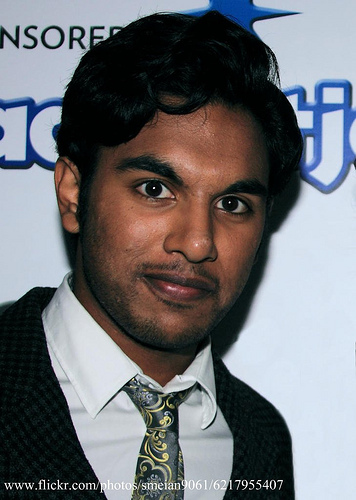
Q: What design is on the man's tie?
A: Paisley.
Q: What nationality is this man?
A: Indian.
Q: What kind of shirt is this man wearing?
A: Dress.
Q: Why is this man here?
A: Famous.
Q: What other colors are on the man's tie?
A: Gold, grey, black.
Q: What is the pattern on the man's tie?
A: Paisley.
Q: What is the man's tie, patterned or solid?
A: Patterned.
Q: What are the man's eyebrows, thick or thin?
A: Thick.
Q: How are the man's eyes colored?
A: Brown.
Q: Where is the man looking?
A: Ahead.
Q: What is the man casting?
A: Shadow.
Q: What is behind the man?
A: Writing.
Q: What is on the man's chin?
A: Hair.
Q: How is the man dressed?
A: Formal.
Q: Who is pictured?
A: A man.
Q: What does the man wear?
A: A tie.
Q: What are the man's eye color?
A: Brown.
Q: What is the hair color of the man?
A: Black.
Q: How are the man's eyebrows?
A: Bushy.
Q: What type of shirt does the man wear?
A: Collared.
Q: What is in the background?
A: White sign.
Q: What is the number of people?
A: One.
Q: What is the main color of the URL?
A: White.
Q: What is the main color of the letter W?
A: White.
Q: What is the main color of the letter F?
A: White.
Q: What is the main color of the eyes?
A: Brown.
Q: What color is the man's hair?
A: Black.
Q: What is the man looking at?
A: The camera.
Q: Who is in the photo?
A: A man.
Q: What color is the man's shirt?
A: White.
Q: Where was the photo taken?
A: An award show.